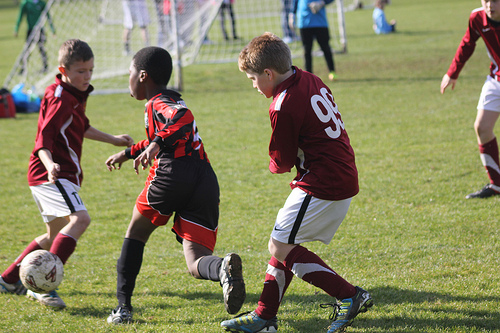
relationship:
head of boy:
[128, 47, 174, 101] [107, 47, 245, 326]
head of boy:
[54, 37, 96, 92] [0, 33, 139, 313]